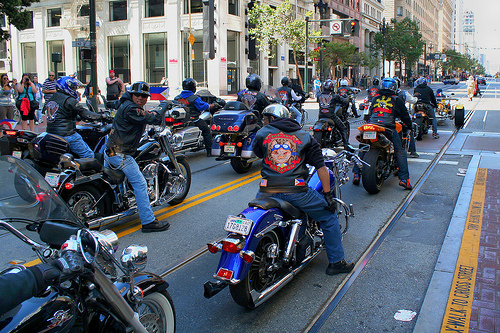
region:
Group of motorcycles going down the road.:
[0, 44, 493, 325]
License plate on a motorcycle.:
[220, 213, 255, 235]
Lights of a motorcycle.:
[98, 223, 151, 284]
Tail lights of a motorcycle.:
[200, 230, 253, 270]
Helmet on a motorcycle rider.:
[263, 100, 298, 123]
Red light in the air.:
[304, 14, 385, 40]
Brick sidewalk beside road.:
[453, 253, 495, 331]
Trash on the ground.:
[390, 303, 415, 325]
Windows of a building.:
[133, 28, 180, 96]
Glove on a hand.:
[47, 253, 91, 280]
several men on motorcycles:
[1, 31, 466, 326]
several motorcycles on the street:
[6, 35, 471, 326]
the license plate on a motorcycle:
[220, 210, 256, 237]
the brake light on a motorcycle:
[218, 234, 240, 257]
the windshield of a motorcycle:
[0, 157, 82, 231]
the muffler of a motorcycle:
[248, 263, 303, 310]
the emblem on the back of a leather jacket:
[259, 130, 304, 174]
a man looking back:
[126, 82, 154, 112]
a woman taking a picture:
[18, 71, 38, 103]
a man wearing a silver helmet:
[255, 100, 292, 133]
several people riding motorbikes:
[0, 68, 477, 330]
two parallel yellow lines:
[11, 154, 271, 264]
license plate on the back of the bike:
[222, 214, 252, 234]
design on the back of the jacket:
[371, 93, 396, 122]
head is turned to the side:
[128, 83, 152, 109]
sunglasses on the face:
[130, 90, 150, 102]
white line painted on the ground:
[406, 153, 461, 169]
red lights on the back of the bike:
[200, 233, 255, 266]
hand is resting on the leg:
[319, 188, 338, 212]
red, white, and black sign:
[326, 18, 346, 39]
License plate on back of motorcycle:
[215, 209, 257, 239]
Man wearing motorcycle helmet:
[122, 76, 154, 110]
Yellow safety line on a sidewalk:
[447, 245, 484, 320]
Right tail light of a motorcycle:
[237, 246, 266, 268]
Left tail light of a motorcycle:
[204, 235, 223, 257]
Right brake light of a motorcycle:
[216, 232, 246, 263]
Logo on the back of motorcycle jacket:
[255, 128, 305, 182]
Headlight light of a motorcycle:
[117, 241, 159, 281]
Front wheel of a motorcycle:
[111, 265, 183, 331]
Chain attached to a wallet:
[102, 146, 133, 175]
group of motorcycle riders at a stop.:
[3, 62, 442, 331]